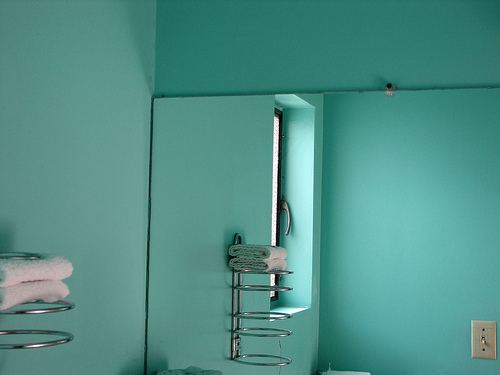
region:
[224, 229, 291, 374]
towel rack with five rings.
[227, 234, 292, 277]
Two white folded towels on towel rack.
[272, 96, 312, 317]
Closed window.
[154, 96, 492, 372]
Mirror reflecting the bathroom.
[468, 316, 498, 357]
A light switch on the wall.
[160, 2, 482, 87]
The wall color is turquoise.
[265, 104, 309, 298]
Sunlight is coming from the window.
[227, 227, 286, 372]
The reflection of a towel rack on the mirror.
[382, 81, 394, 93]
screw holding the mirror in place.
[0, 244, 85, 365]
Towel rack is made of metal.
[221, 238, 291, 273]
two folded white towels on metal rack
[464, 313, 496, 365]
white light switch on mint green wall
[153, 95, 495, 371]
mint green painted walls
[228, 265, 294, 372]
metal towel wall rack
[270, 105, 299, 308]
rectangular window on wall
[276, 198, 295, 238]
silver window handle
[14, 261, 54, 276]
fleeced white material on towel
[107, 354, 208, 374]
shadow on wall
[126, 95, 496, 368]
large wall mirror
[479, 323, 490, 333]
black bolt on wall light switch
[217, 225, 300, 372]
silve chrome towel hanger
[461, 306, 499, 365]
cream light switch plate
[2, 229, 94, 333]
two folded towels in holder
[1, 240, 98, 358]
silver towel holder with towels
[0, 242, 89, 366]
towel holder with two towels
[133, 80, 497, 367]
large wall mounted mirror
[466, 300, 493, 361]
light switch cover with lines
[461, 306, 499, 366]
light switch in off position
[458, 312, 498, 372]
light switch turned off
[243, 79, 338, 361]
tall bathroom window with handle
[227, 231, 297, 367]
a metal towel rack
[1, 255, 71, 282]
a folded towel that is white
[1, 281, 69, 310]
a folded towel that is white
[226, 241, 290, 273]
two white folded towels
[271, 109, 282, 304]
a sliver of a window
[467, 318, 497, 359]
a lightswitch on a wall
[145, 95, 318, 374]
a section of green wall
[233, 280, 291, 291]
a metal circle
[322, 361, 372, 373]
white wall under paint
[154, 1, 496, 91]
a section of green wall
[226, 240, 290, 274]
a stack of white towels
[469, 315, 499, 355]
a white light switch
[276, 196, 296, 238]
a metal window handle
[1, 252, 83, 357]
two towels on a towel rack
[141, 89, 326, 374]
a teal bathroom wall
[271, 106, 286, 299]
light seeping through a closed window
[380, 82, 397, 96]
a metal hinge on the wall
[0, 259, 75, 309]
white towels on a metal rack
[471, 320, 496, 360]
a beige light switch